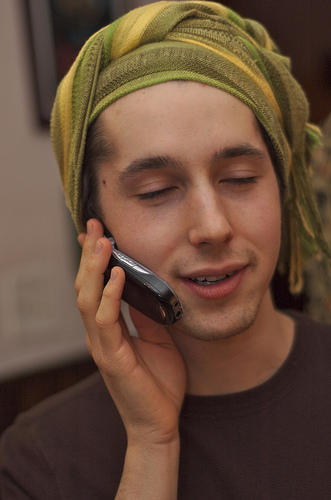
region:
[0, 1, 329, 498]
a man talking on a cell phone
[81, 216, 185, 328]
a flip cell phone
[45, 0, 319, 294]
a yellow and green head covering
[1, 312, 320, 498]
a brown t-shirt on a man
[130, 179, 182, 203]
a mans closed eye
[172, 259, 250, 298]
a mans mouth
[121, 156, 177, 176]
a mans bushy eyebrown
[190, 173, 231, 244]
a mans nose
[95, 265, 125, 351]
a mans pink finger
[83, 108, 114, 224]
a mans dark brown hair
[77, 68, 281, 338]
the man's face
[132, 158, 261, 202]
the man's two eyes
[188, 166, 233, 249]
the man's nose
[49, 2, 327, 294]
the fabric on the man's head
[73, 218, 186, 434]
the man's right hand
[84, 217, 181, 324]
the cell phone in the man's hand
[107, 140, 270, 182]
the man's eyebrows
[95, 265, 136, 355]
the pinky on the man's hand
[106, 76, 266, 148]
the man's forehead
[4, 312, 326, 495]
the man's brown shirt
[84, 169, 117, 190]
brown mole on boy's face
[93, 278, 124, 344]
boy's pinkie finger on hand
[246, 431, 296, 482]
brown tshirt on boy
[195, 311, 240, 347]
dark stubble on boy's chin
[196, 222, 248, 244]
nostrils on boys nose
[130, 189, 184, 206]
dark black boy's eyelashes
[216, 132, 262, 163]
dark black eyebrows on boy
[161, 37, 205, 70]
multicolored green head scarf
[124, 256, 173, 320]
black and silver flip phone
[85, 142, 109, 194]
boy's dark brown hair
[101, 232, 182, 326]
black cell phone in man's hand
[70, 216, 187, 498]
right hand of the man holding a cell phone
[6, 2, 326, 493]
man talking on a cellphone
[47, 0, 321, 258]
green bandana on man's head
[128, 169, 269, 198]
the man's eyes are closed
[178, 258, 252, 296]
the man's mouth is slightly open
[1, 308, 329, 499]
brown shirt on the man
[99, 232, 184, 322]
the cellphone is flipped open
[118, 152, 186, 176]
the man's right eyebrow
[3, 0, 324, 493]
The man is talking on the cell phone.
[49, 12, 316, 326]
The man has a green and yellow head covering.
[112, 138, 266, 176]
The man has two eye brows.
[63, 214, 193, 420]
A phone is in the man's hand.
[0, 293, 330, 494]
The man is wearing a brown shirt.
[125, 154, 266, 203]
The man's eyes are closed.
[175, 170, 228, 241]
The man has a nose.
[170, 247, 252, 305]
The man is smiling.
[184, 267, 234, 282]
The man's teeth are showing.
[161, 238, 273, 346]
The man has stubbly hair growth on the face.